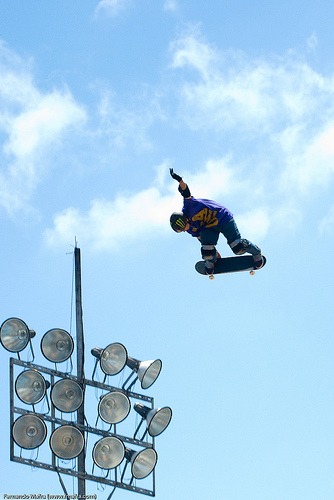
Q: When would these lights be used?
A: For evening events.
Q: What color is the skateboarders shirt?
A: Blue.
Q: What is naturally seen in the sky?
A: Clouds.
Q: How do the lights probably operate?
A: By electricity.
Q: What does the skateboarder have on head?
A: Helmet.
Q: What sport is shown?
A: Skateboarding.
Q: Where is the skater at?
A: Mid air.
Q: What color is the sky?
A: Blue.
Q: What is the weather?
A: Few clouds and sunny.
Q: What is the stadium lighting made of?
A: Metal.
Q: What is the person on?
A: Skateboard.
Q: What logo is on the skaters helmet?
A: Monster.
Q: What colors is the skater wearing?
A: Blue and yellow.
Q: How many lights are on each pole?
A: 12.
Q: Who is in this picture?
A: A guy on a skateboard.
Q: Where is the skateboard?
A: In the sky.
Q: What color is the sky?
A: Blue with a few white clouds.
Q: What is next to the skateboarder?
A: Big round lights.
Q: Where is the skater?
A: In the air.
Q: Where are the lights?
A: On a lightpole.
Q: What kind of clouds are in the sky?
A: Wispy white clouds.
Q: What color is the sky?
A: Light blue.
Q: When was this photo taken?
A: Midday.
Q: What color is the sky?
A: Blue.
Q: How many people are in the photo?
A: 1.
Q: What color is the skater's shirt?
A: Purple.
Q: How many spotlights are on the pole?
A: 12.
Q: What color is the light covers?
A: Clear.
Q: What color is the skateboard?
A: Black.